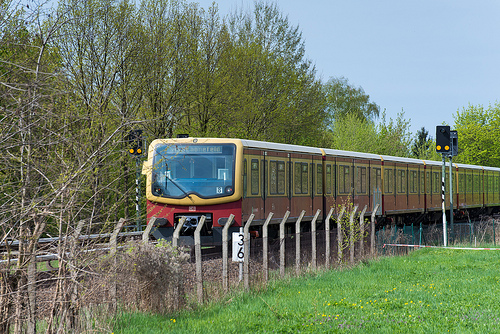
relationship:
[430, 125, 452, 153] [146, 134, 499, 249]
light signal next to train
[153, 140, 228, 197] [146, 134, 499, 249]
windshield on train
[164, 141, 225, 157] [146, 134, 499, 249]
digital  board on train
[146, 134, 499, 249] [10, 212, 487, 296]
train on tracks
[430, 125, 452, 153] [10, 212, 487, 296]
light signal beside tracks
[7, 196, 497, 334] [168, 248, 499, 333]
fence beside grass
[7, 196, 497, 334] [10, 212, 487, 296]
fence beside tracks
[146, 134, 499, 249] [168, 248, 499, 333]
train traveling beside grass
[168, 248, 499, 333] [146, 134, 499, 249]
grass to right of train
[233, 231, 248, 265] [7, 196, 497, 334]
sign on fence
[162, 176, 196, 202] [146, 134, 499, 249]
windshield wiper on train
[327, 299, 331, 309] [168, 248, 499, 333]
flower in grass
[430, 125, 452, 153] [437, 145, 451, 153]
light signal with lights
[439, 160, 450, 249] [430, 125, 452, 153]
pole supporting light signal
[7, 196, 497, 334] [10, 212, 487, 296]
fence by tracks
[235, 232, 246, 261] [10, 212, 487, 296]
36 by tracks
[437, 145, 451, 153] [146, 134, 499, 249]
lights to left of train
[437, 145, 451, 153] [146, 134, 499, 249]
lights to right of train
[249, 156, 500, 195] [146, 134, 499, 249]
windows on train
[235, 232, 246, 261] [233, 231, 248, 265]
36 written on sign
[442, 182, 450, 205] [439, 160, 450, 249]
stripes on pole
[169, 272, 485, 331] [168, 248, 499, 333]
flowers in grass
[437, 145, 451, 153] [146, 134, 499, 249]
lights by train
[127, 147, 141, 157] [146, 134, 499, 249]
lights by train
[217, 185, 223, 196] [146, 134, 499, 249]
8 on train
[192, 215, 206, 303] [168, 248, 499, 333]
post near grass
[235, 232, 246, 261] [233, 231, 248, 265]
36 on sign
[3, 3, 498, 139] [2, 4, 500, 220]
sky above trees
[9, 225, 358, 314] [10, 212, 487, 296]
pebbles near tracks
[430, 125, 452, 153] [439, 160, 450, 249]
light signal on pole